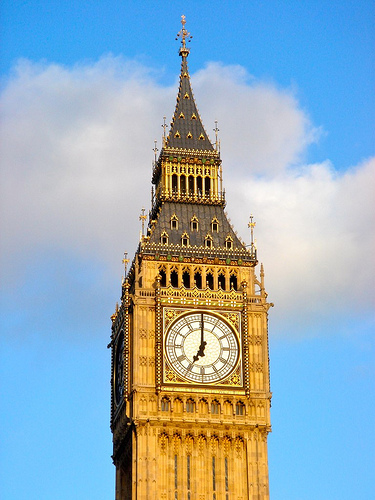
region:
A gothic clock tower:
[94, 14, 287, 489]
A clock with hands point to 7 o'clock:
[165, 310, 240, 380]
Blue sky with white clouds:
[7, 6, 373, 196]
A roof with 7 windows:
[147, 203, 246, 249]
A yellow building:
[105, 246, 274, 499]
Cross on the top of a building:
[178, 13, 188, 21]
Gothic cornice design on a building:
[137, 395, 270, 426]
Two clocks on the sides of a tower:
[108, 309, 249, 404]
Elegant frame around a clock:
[154, 285, 253, 396]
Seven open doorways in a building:
[146, 262, 245, 295]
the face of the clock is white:
[160, 300, 245, 390]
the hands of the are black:
[189, 311, 211, 363]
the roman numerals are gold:
[168, 309, 239, 385]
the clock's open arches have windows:
[158, 392, 248, 418]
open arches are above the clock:
[148, 256, 254, 298]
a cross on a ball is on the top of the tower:
[178, 13, 189, 24]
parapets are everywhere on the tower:
[105, 135, 271, 309]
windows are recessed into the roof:
[158, 203, 241, 250]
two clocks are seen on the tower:
[108, 283, 257, 415]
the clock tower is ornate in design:
[106, 15, 275, 491]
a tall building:
[128, 65, 349, 481]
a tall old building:
[101, 67, 316, 489]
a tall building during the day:
[97, 59, 373, 487]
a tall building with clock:
[84, 173, 284, 429]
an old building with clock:
[94, 210, 306, 497]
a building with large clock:
[97, 231, 334, 491]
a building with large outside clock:
[86, 219, 277, 498]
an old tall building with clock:
[125, 242, 294, 479]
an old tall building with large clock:
[103, 244, 302, 463]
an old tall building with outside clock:
[125, 259, 316, 497]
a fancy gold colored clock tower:
[105, 11, 274, 497]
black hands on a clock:
[192, 320, 207, 362]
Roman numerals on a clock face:
[165, 314, 236, 381]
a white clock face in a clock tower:
[165, 312, 239, 377]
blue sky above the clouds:
[2, 0, 373, 167]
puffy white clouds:
[1, 64, 371, 311]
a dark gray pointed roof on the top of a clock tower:
[165, 54, 226, 153]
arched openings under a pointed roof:
[162, 162, 215, 200]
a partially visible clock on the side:
[111, 321, 126, 408]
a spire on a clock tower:
[174, 10, 198, 60]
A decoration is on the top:
[156, 8, 209, 68]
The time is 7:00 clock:
[143, 275, 264, 404]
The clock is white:
[146, 294, 252, 402]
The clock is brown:
[90, 6, 279, 495]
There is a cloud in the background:
[7, 16, 357, 402]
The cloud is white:
[0, 25, 348, 377]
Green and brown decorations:
[140, 116, 222, 176]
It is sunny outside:
[8, 9, 345, 399]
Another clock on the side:
[80, 295, 148, 407]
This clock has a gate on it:
[89, 206, 307, 320]